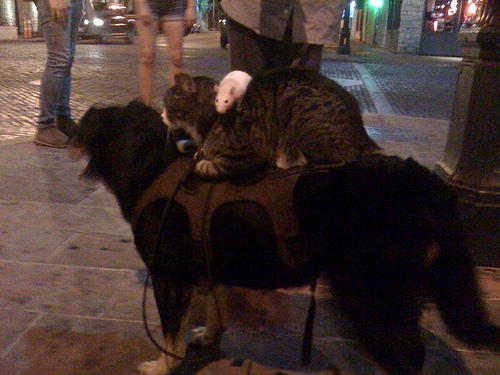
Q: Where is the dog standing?
A: On the sidewalk.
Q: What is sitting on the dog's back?
A: A cat.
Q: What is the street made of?
A: Cobblestone.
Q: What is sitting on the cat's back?
A: A mouse.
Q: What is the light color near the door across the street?
A: Green.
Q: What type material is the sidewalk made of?
A: Tiles.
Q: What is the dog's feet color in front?
A: White.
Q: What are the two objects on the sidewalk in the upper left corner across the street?
A: Safety cones.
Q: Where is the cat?
A: On top of the dog.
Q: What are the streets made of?
A: Cobblestone.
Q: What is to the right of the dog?
A: Iron post.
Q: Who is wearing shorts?
A: Person in the middle.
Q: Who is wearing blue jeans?
A: Person on the left.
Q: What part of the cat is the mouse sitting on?
A: Neck.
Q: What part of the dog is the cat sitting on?
A: Back.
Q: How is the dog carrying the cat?
A: On the back.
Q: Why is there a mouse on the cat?
A: For show in a photo.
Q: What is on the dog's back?
A: A cat and mouse.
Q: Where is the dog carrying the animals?
A: City sidewalk.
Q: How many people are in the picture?
A: Three.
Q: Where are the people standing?
A: On the sidewalk.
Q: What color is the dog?
A: Black.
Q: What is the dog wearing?
A: A black vest.